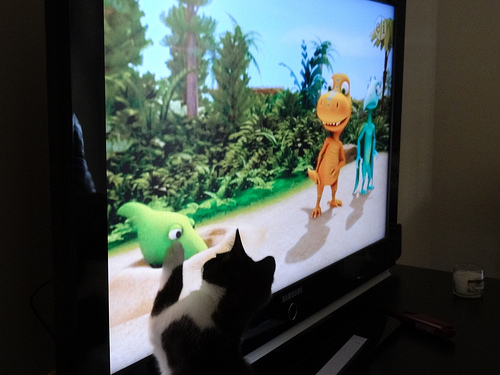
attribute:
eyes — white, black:
[327, 86, 347, 94]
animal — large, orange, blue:
[306, 65, 355, 223]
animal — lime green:
[114, 191, 208, 258]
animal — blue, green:
[356, 75, 379, 192]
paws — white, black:
[163, 243, 185, 269]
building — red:
[249, 82, 287, 96]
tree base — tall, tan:
[185, 37, 199, 122]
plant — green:
[166, 159, 232, 191]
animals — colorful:
[294, 51, 386, 216]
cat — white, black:
[145, 226, 278, 373]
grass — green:
[233, 192, 264, 203]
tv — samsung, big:
[65, 7, 406, 302]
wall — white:
[435, 19, 478, 68]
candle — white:
[449, 259, 489, 303]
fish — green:
[159, 212, 203, 249]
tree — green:
[209, 27, 250, 118]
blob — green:
[74, 114, 95, 191]